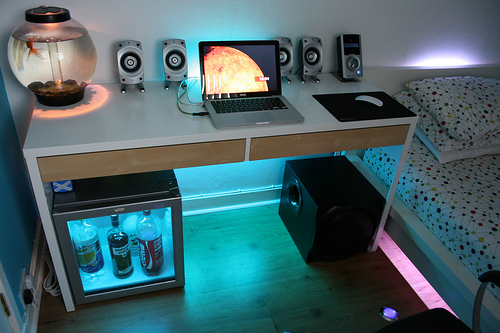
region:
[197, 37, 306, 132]
a black and silver laptop computer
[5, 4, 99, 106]
a fish tank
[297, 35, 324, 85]
a black and silver speaker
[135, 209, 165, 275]
bottle of soda in the refrigerator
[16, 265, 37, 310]
black and white plugs in the outlet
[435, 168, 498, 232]
blue, red, yellow and green colors on white sheets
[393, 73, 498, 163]
a pillow can be seen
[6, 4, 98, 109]
a gold fish in the fish tank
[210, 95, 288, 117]
a black keyboard on the laptop computer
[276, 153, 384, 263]
a black sub woofer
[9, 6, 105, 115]
a round fishtank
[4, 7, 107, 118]
a goldfish bowl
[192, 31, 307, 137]
a small laptop computer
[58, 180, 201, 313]
square mini-fridge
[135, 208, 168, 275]
bottle of Coca-Cola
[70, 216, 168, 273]
four bottles of drink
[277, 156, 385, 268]
a black sub-woofer under the desk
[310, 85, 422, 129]
a black mousepad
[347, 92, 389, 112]
a white mouse on a mousepad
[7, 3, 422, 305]
a neatly arranged desk with computer and a fish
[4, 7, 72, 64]
goldfish in aquarium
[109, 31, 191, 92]
two speakers on desk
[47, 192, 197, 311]
beverages in mini fridge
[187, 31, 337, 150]
silver laptop on top of desk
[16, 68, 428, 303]
white desk with brown drawers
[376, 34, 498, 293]
multi-color sheets and pillow cases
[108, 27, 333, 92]
four desktop speakers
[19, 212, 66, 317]
white electrical cord on floor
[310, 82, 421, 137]
white mouse on black mousepad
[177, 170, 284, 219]
white painted baseboards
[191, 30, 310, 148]
laptop screen showing a sun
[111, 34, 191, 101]
computer speakers on desk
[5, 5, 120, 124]
fish bowl with one goldfish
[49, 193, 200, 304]
small refrigerator under the desk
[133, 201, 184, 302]
almost empty two liter bottle of coke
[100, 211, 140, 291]
half empty glass bottle of liquor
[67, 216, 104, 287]
almost full two liter bottle of soda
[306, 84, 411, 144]
black mouse pad with a moon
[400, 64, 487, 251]
multi-colored polka dotted sheets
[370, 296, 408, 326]
cell phone on the floor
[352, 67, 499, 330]
a bed with dots and lines on sheet and pillows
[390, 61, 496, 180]
three stacked pillows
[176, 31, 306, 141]
an open laptop computer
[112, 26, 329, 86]
four silver and black computer speakers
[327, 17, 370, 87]
an alarm clock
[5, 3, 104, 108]
an aquarium with a gold fish swimming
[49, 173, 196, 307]
a mini fridge with drinks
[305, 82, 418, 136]
a black mousepad with white mouse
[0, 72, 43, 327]
a wall painted blue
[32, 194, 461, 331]
a wooden floor